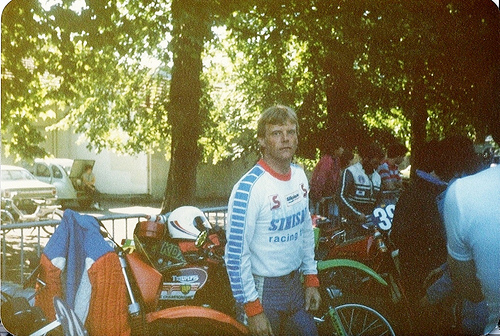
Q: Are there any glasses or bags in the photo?
A: No, there are no glasses or bags.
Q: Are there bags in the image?
A: No, there are no bags.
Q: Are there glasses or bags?
A: No, there are no bags or glasses.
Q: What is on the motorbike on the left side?
A: The jacket is on the motorbike.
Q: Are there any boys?
A: No, there are no boys.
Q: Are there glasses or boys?
A: No, there are no boys or glasses.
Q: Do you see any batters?
A: No, there are no batters.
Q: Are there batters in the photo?
A: No, there are no batters.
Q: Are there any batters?
A: No, there are no batters.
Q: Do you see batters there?
A: No, there are no batters.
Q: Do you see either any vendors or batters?
A: No, there are no batters or vendors.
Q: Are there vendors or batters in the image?
A: No, there are no batters or vendors.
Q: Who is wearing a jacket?
A: The man is wearing a jacket.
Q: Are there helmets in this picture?
A: Yes, there is a helmet.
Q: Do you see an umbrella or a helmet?
A: Yes, there is a helmet.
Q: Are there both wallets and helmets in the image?
A: No, there is a helmet but no wallets.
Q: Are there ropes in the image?
A: No, there are no ropes.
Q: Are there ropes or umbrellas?
A: No, there are no ropes or umbrellas.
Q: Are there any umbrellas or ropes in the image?
A: No, there are no ropes or umbrellas.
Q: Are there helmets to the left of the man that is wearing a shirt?
A: Yes, there is a helmet to the left of the man.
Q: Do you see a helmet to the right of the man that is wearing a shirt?
A: No, the helmet is to the left of the man.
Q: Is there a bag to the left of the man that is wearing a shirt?
A: No, there is a helmet to the left of the man.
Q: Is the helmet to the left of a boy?
A: No, the helmet is to the left of the man.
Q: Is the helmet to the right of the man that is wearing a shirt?
A: No, the helmet is to the left of the man.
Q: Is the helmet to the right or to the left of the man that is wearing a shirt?
A: The helmet is to the left of the man.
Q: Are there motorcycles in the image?
A: Yes, there is a motorcycle.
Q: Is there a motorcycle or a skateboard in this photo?
A: Yes, there is a motorcycle.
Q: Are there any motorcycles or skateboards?
A: Yes, there is a motorcycle.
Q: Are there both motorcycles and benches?
A: No, there is a motorcycle but no benches.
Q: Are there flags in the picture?
A: No, there are no flags.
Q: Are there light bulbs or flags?
A: No, there are no flags or light bulbs.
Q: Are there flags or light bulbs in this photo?
A: No, there are no flags or light bulbs.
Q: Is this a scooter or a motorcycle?
A: This is a motorcycle.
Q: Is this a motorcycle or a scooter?
A: This is a motorcycle.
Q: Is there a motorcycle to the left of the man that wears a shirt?
A: Yes, there is a motorcycle to the left of the man.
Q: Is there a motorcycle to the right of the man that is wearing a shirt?
A: No, the motorcycle is to the left of the man.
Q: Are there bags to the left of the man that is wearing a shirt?
A: No, there is a motorcycle to the left of the man.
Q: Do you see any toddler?
A: No, there are no toddlers.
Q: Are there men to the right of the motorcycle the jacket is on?
A: Yes, there is a man to the right of the motorcycle.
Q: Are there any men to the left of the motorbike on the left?
A: No, the man is to the right of the motorbike.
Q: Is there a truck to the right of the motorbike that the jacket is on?
A: No, there is a man to the right of the motorbike.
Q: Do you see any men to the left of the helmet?
A: No, the man is to the right of the helmet.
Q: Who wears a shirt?
A: The man wears a shirt.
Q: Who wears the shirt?
A: The man wears a shirt.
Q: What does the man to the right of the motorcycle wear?
A: The man wears a shirt.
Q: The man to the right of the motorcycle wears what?
A: The man wears a shirt.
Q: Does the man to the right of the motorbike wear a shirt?
A: Yes, the man wears a shirt.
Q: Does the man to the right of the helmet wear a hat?
A: No, the man wears a shirt.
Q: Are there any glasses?
A: No, there are no glasses.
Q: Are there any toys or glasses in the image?
A: No, there are no glasses or toys.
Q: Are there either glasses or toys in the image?
A: No, there are no glasses or toys.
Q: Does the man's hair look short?
A: Yes, the hair is short.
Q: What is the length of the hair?
A: The hair is short.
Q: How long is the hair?
A: The hair is short.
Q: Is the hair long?
A: No, the hair is short.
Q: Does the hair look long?
A: No, the hair is short.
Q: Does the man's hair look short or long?
A: The hair is short.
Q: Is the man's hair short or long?
A: The hair is short.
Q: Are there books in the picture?
A: No, there are no books.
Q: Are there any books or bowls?
A: No, there are no books or bowls.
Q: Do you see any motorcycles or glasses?
A: Yes, there is a motorcycle.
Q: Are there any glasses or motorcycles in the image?
A: Yes, there is a motorcycle.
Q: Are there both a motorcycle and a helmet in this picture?
A: Yes, there are both a motorcycle and a helmet.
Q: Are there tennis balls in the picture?
A: No, there are no tennis balls.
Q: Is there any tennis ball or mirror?
A: No, there are no tennis balls or mirrors.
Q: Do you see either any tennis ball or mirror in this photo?
A: No, there are no tennis balls or mirrors.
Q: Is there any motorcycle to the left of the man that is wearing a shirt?
A: Yes, there is a motorcycle to the left of the man.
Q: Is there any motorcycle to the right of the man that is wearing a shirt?
A: No, the motorcycle is to the left of the man.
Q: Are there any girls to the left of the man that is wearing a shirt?
A: No, there is a motorcycle to the left of the man.